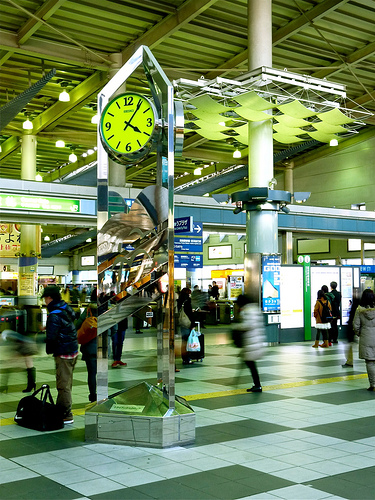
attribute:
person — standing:
[33, 279, 86, 424]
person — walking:
[42, 287, 102, 449]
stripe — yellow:
[180, 360, 361, 402]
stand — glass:
[58, 149, 245, 419]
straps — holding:
[30, 383, 56, 405]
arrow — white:
[67, 37, 207, 203]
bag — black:
[14, 386, 71, 431]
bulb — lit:
[55, 84, 73, 102]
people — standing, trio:
[312, 276, 343, 347]